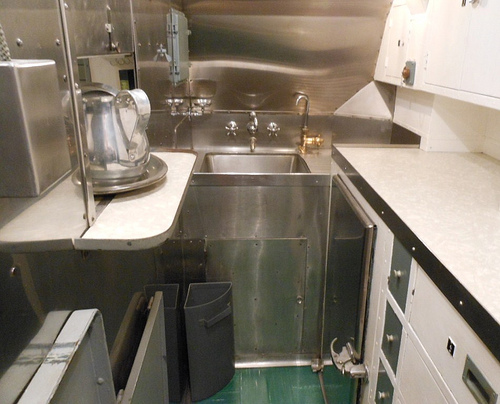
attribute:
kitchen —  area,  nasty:
[19, 26, 499, 401]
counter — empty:
[331, 144, 498, 327]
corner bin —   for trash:
[183, 278, 234, 396]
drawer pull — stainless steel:
[392, 267, 402, 280]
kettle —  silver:
[57, 79, 176, 167]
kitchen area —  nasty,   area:
[181, 48, 391, 374]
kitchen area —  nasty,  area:
[1, 0, 498, 402]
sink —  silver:
[160, 80, 330, 227]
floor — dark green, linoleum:
[208, 362, 355, 401]